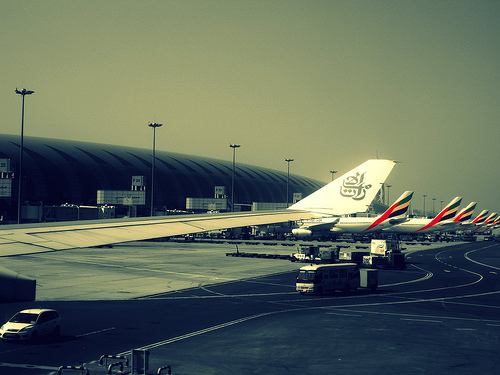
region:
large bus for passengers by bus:
[302, 260, 377, 308]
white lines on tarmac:
[173, 297, 320, 344]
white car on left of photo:
[7, 297, 62, 372]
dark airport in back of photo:
[46, 127, 276, 232]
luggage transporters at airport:
[293, 237, 345, 262]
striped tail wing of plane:
[389, 189, 419, 234]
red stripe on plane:
[378, 201, 388, 234]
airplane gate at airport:
[121, 169, 160, 219]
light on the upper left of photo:
[14, 76, 49, 113]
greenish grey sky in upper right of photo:
[356, 7, 484, 140]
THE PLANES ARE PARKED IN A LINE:
[265, 185, 499, 241]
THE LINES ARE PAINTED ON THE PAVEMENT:
[0, 242, 499, 374]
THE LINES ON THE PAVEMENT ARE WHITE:
[0, 237, 499, 372]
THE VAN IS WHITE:
[0, 300, 65, 347]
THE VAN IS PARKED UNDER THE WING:
[0, 301, 66, 354]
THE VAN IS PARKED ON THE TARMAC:
[0, 300, 65, 343]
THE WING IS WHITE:
[0, 153, 400, 262]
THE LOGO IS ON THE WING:
[338, 167, 380, 206]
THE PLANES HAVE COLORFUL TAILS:
[366, 185, 498, 234]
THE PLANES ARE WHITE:
[288, 187, 499, 242]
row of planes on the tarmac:
[322, 175, 497, 250]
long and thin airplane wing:
[10, 152, 397, 262]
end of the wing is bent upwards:
[269, 134, 407, 232]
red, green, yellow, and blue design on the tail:
[367, 180, 420, 242]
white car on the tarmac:
[0, 300, 63, 346]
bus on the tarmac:
[285, 245, 360, 303]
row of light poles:
[4, 77, 329, 228]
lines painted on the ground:
[405, 250, 497, 312]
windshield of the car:
[10, 308, 38, 323]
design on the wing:
[333, 166, 369, 202]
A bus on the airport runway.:
[293, 259, 395, 304]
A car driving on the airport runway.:
[8, 288, 69, 353]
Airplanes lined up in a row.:
[274, 186, 491, 241]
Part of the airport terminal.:
[23, 131, 331, 216]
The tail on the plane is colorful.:
[379, 178, 419, 236]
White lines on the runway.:
[196, 276, 312, 336]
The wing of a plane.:
[11, 200, 285, 248]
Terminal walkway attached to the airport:
[98, 173, 152, 213]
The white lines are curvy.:
[406, 244, 499, 301]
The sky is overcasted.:
[73, 40, 433, 133]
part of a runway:
[252, 306, 284, 339]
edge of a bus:
[312, 257, 338, 277]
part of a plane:
[345, 213, 369, 227]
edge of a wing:
[401, 186, 417, 207]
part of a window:
[293, 258, 318, 290]